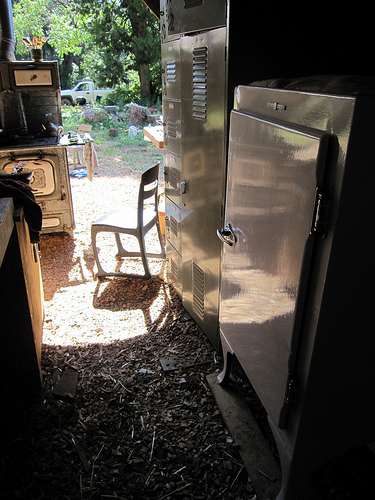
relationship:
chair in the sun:
[74, 160, 170, 285] [61, 177, 145, 321]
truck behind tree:
[59, 79, 116, 109] [76, 0, 163, 109]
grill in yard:
[72, 94, 89, 109] [31, 95, 183, 189]